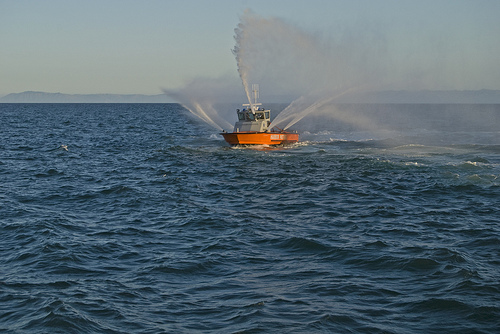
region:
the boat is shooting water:
[194, 71, 343, 180]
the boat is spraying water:
[175, 24, 413, 233]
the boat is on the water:
[189, 31, 342, 212]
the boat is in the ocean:
[168, 30, 366, 190]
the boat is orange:
[199, 72, 326, 184]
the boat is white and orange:
[190, 35, 401, 212]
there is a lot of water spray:
[146, 3, 443, 199]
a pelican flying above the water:
[38, 120, 107, 165]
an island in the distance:
[3, 72, 498, 116]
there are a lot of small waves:
[0, 105, 499, 331]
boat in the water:
[213, 93, 309, 152]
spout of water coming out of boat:
[185, 81, 232, 138]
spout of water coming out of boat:
[229, 11, 295, 113]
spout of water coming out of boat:
[261, 65, 392, 145]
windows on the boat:
[235, 109, 269, 121]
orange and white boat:
[218, 80, 314, 155]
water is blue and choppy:
[2, 100, 497, 332]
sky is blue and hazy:
[3, 1, 498, 102]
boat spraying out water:
[158, 7, 430, 160]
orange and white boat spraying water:
[155, 1, 492, 160]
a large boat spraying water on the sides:
[164, 8, 411, 160]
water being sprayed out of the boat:
[223, 29, 318, 84]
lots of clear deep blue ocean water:
[75, 113, 158, 292]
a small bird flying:
[52, 138, 79, 156]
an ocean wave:
[274, 230, 329, 253]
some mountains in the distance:
[7, 85, 152, 112]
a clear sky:
[16, 6, 166, 80]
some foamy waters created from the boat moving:
[247, 141, 305, 151]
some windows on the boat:
[235, 110, 268, 120]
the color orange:
[241, 130, 266, 142]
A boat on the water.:
[199, 92, 320, 161]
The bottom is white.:
[214, 130, 305, 158]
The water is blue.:
[208, 225, 409, 284]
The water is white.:
[185, 65, 315, 119]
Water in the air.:
[245, 48, 350, 98]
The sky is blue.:
[20, 0, 191, 61]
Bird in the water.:
[30, 136, 86, 161]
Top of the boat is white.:
[230, 103, 277, 132]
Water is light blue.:
[324, 114, 445, 148]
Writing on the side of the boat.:
[252, 131, 324, 146]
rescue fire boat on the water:
[156, 10, 411, 149]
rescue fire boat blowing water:
[163, 8, 372, 149]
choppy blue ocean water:
[13, 160, 495, 326]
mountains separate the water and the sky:
[2, 85, 496, 105]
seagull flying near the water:
[57, 140, 71, 152]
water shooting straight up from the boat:
[227, 6, 297, 103]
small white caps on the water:
[338, 149, 497, 171]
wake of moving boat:
[250, 138, 338, 153]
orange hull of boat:
[221, 131, 301, 148]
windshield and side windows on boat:
[233, 108, 273, 121]